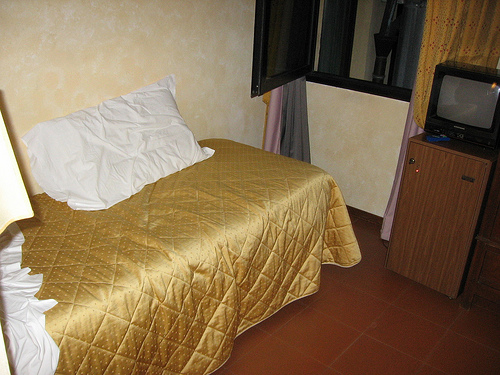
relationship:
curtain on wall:
[265, 82, 317, 171] [4, 3, 268, 150]